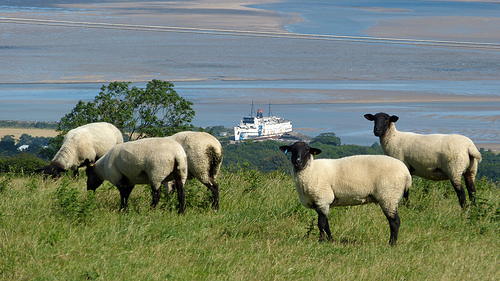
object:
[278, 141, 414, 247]
sheep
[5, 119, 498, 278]
field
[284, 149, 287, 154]
tag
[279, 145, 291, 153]
ear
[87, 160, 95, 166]
spot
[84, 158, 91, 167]
ear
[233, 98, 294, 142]
ship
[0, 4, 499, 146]
water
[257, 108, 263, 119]
chimney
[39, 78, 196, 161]
tree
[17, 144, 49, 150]
roof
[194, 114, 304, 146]
port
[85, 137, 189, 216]
sheep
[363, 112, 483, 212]
sheep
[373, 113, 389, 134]
face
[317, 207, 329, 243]
legs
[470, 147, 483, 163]
hair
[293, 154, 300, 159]
hose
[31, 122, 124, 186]
sheep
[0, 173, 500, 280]
grass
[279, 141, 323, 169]
head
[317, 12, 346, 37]
sky